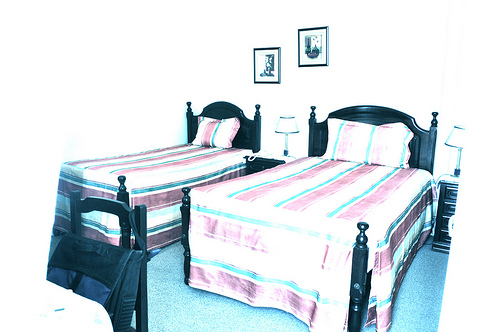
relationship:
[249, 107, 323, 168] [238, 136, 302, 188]
lamp on stand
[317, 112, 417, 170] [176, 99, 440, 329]
pillow on bed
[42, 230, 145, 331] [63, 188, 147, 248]
bag in chair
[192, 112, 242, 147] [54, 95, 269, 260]
pillow on a bed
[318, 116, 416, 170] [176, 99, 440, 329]
pillow on a bed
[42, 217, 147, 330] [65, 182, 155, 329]
bag on chair